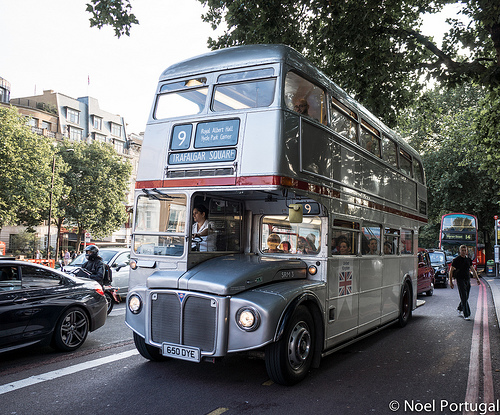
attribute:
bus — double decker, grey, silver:
[120, 37, 432, 388]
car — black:
[33, 264, 163, 394]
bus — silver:
[119, 87, 363, 385]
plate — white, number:
[158, 338, 205, 365]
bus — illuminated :
[135, 50, 465, 390]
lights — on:
[122, 290, 258, 336]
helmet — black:
[82, 245, 99, 260]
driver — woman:
[187, 206, 214, 254]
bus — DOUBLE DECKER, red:
[436, 213, 478, 273]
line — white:
[6, 351, 133, 400]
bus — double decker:
[437, 211, 485, 276]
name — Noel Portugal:
[400, 400, 499, 413]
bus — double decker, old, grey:
[110, 27, 449, 385]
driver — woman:
[162, 203, 224, 254]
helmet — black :
[82, 241, 100, 263]